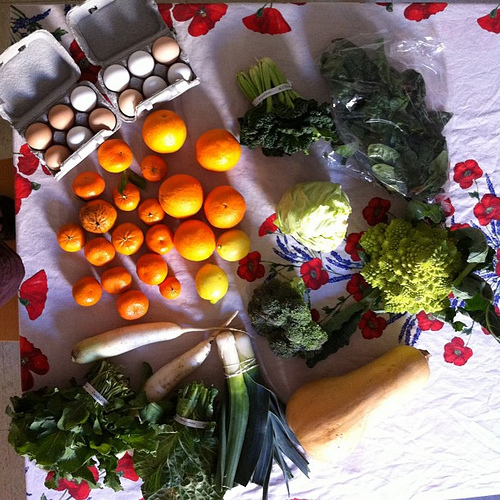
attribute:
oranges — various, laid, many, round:
[138, 110, 243, 268]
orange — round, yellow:
[187, 121, 245, 175]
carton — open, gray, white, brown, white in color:
[8, 31, 212, 184]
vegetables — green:
[253, 28, 483, 458]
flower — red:
[13, 265, 56, 323]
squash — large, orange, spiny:
[352, 206, 473, 331]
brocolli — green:
[244, 268, 334, 369]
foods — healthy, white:
[5, 4, 494, 493]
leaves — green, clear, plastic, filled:
[298, 21, 469, 226]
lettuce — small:
[10, 363, 246, 497]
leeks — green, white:
[206, 318, 318, 500]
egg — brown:
[151, 30, 181, 60]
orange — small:
[152, 173, 206, 223]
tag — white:
[78, 374, 118, 411]